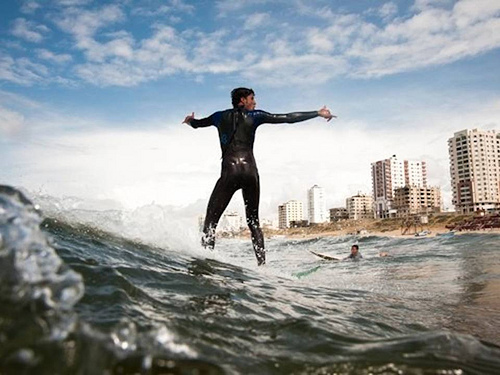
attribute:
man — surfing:
[179, 84, 345, 262]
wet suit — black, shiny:
[214, 111, 262, 197]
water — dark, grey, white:
[42, 279, 468, 344]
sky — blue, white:
[0, 3, 191, 111]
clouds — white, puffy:
[362, 22, 448, 71]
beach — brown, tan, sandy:
[293, 213, 465, 239]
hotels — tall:
[282, 127, 496, 215]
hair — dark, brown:
[229, 86, 255, 101]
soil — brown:
[355, 223, 366, 228]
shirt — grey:
[353, 252, 362, 261]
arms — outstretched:
[180, 107, 323, 131]